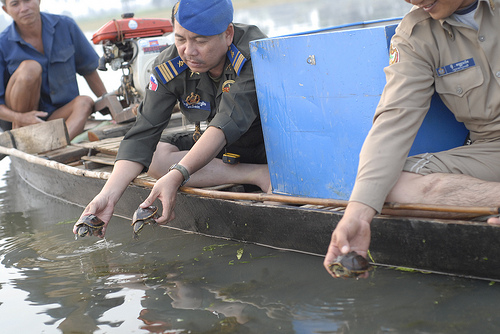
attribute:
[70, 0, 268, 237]
man — uniformed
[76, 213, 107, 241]
turtle — small, being held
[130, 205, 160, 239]
turtle — small, behing held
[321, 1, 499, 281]
other man — brown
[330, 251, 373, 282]
turtle — small, being held, brown, baby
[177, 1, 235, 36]
beret — blue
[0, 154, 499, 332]
water — gray, dirty, murky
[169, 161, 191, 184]
watch — silver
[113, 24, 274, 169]
uniform — olive colored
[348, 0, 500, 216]
uniform — khaki colored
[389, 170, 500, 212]
man's leg — hairy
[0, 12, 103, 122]
shirt — blue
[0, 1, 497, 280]
men — sitting down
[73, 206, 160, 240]
two turtles — brown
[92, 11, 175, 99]
boat motor — red, old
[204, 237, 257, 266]
vegetation — green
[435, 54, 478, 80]
id — blue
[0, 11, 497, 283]
boat — small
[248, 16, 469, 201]
box — large, blue, big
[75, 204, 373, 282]
three turtles — babies, being released, about to be free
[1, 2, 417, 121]
sky — bright, clear